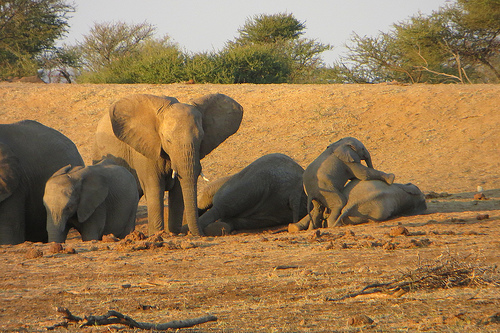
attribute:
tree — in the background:
[351, 12, 488, 87]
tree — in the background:
[244, 11, 314, 84]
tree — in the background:
[171, 44, 301, 79]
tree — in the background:
[80, 20, 163, 78]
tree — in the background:
[0, 3, 74, 85]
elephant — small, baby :
[293, 132, 398, 234]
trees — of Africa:
[1, 37, 498, 79]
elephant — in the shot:
[338, 174, 427, 222]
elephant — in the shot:
[300, 135, 397, 230]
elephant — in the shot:
[201, 148, 309, 234]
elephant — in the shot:
[38, 160, 145, 245]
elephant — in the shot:
[0, 109, 92, 241]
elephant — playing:
[287, 128, 387, 250]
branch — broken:
[46, 308, 223, 329]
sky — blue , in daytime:
[62, 2, 457, 58]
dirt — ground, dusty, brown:
[412, 109, 487, 154]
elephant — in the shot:
[87, 94, 243, 239]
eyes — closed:
[158, 120, 209, 146]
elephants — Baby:
[293, 115, 442, 247]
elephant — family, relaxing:
[42, 162, 139, 241]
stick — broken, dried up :
[49, 303, 228, 331]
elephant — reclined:
[323, 177, 431, 227]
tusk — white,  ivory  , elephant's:
[159, 163, 185, 184]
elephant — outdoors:
[343, 177, 430, 224]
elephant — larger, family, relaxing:
[87, 85, 242, 255]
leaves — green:
[178, 35, 247, 75]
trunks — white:
[167, 166, 224, 191]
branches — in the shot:
[325, 240, 497, 305]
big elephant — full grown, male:
[106, 71, 236, 241]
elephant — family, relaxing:
[201, 151, 305, 231]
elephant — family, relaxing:
[298, 137, 395, 224]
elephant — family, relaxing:
[292, 171, 427, 228]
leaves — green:
[312, 45, 333, 51]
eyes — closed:
[152, 118, 223, 151]